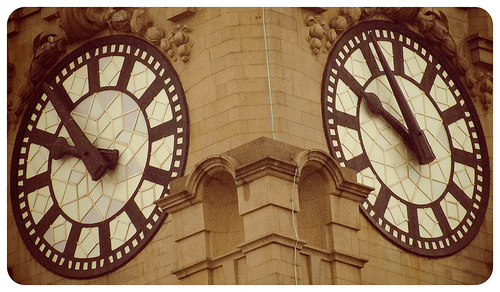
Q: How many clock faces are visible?
A: Two.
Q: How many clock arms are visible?
A: Four.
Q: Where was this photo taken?
A: Near a clock tower.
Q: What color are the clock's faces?
A: White.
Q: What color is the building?
A: Brown.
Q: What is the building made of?
A: Bricks.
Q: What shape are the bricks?
A: Rectangle.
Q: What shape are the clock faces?
A: Circular.